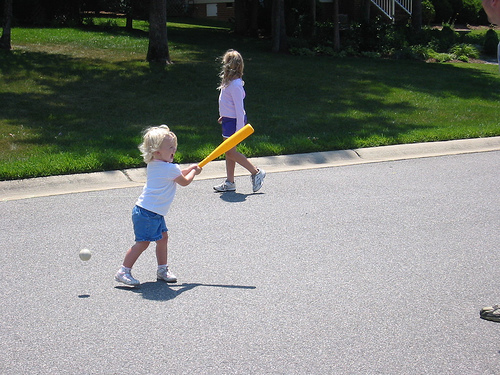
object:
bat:
[195, 117, 257, 172]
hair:
[220, 52, 242, 79]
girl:
[206, 47, 272, 202]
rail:
[373, 0, 395, 20]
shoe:
[211, 175, 239, 195]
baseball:
[75, 248, 93, 261]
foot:
[148, 257, 181, 285]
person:
[470, 298, 500, 324]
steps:
[389, 10, 416, 30]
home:
[183, 0, 241, 28]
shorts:
[221, 118, 245, 135]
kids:
[113, 121, 214, 289]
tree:
[136, 0, 182, 74]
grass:
[2, 21, 500, 176]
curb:
[323, 137, 377, 164]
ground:
[0, 151, 500, 366]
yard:
[0, 0, 500, 205]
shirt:
[214, 77, 248, 121]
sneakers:
[111, 271, 139, 286]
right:
[402, 155, 464, 223]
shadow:
[72, 290, 100, 304]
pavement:
[0, 140, 500, 374]